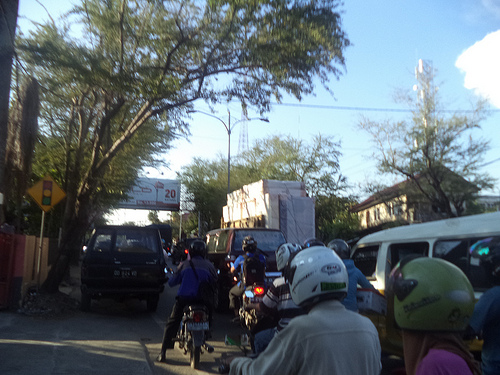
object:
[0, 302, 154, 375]
sidewalk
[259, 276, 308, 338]
shirt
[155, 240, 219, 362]
person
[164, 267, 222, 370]
motorcycle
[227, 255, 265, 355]
motorcycle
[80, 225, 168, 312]
vehicle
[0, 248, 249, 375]
road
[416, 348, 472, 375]
purple shirt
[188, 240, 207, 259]
helmet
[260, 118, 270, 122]
lamp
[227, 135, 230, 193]
pole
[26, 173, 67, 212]
sign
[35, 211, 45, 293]
pole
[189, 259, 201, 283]
strap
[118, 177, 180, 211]
billboard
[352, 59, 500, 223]
tree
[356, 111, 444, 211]
branches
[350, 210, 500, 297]
white van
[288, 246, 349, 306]
helmet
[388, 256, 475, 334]
helmet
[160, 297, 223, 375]
curb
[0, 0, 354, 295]
tree